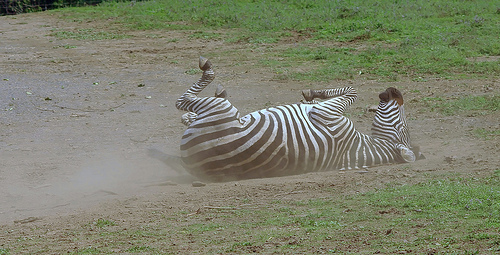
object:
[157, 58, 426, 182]
zebra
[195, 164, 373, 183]
back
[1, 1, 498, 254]
dirt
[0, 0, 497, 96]
up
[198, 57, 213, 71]
hoof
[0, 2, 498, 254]
ground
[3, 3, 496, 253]
light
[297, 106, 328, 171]
stripe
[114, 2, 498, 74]
grass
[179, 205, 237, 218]
stick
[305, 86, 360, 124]
leg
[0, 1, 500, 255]
air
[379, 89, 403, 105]
nose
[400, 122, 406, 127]
eye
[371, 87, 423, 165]
head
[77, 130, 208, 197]
dust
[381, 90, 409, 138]
face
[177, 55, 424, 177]
side view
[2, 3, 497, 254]
photo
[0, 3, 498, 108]
background